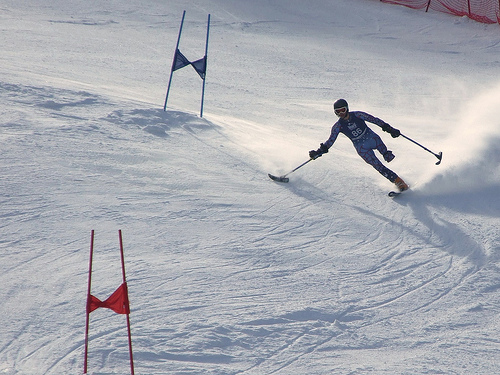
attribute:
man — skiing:
[312, 79, 405, 233]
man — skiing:
[297, 63, 457, 233]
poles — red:
[64, 219, 172, 368]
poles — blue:
[157, 16, 233, 133]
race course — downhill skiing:
[75, 39, 425, 370]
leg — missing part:
[351, 135, 409, 165]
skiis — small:
[251, 160, 293, 194]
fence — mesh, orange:
[406, 3, 490, 29]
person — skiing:
[315, 91, 425, 201]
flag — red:
[49, 269, 153, 325]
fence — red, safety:
[394, 2, 491, 35]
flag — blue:
[154, 22, 204, 104]